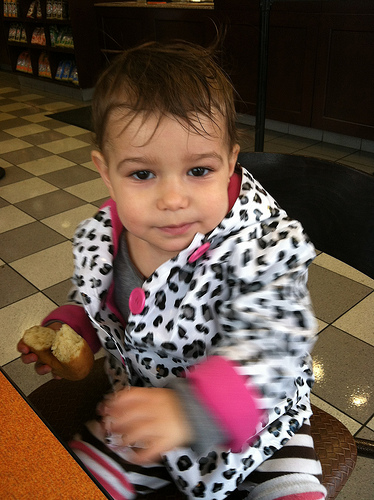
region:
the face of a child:
[131, 72, 216, 235]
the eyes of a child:
[121, 153, 211, 177]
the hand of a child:
[101, 381, 190, 470]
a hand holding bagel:
[10, 306, 97, 394]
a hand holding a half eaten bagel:
[14, 314, 101, 398]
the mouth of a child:
[154, 214, 201, 235]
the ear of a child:
[226, 139, 240, 182]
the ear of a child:
[90, 143, 118, 212]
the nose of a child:
[155, 187, 190, 214]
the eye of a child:
[124, 162, 159, 187]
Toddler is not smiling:
[88, 43, 241, 252]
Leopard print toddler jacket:
[42, 162, 318, 499]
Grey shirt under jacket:
[110, 232, 144, 318]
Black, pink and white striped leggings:
[70, 408, 323, 498]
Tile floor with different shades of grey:
[2, 85, 370, 438]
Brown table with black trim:
[0, 371, 103, 497]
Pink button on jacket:
[128, 287, 145, 315]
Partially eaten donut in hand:
[16, 323, 92, 384]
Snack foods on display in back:
[0, 0, 81, 87]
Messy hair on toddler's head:
[90, 19, 238, 157]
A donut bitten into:
[22, 323, 93, 379]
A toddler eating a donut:
[17, 24, 327, 498]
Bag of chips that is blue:
[55, 62, 63, 78]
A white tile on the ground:
[16, 154, 75, 175]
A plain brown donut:
[20, 323, 92, 378]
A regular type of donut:
[19, 323, 91, 379]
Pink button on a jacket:
[128, 287, 146, 313]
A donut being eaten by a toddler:
[23, 320, 90, 378]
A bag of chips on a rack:
[15, 50, 23, 70]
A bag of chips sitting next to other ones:
[8, 26, 13, 38]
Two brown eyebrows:
[114, 149, 225, 166]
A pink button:
[127, 285, 146, 315]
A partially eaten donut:
[14, 323, 98, 384]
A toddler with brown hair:
[85, 41, 245, 254]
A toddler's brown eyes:
[122, 163, 220, 182]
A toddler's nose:
[154, 179, 193, 212]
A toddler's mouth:
[150, 217, 203, 235]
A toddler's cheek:
[117, 188, 152, 237]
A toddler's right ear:
[88, 148, 117, 203]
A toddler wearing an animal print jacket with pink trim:
[72, 43, 311, 436]